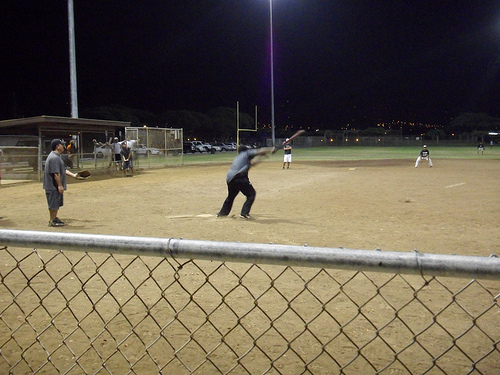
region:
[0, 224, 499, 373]
metal chain link fence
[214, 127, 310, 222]
baseball player in black pants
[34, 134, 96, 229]
large man in grey shorts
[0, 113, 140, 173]
wooden baseball dugout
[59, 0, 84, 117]
large silver metal light pole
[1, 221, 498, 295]
top supporting bar of a chain link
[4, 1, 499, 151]
dark black night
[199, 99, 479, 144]
golden city lights in the distance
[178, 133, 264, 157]
parking lot full of parked cars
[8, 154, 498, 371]
brown dirt base ball field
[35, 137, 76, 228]
man in a gray shirt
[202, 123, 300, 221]
man swinging a baseball bat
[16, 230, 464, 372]
chain link fence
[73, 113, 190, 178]
people in a baseball dugout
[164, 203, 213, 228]
home base on a baseball diamond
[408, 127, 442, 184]
baseball player in white pants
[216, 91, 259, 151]
yellow field goal post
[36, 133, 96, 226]
man holding a brown glove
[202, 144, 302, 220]
man in black pants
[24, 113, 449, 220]
men playing baseball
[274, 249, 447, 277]
Metal fence.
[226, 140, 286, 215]
The man is swinging a baseball bat.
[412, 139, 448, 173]
baseball outfielder.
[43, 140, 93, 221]
A man playing the catcher.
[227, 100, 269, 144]
A field goal.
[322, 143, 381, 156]
A green grass field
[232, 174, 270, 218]
Man wearing black pants.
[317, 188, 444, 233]
Baseball field.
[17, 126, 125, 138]
Baseball dugout.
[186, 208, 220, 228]
Home plate.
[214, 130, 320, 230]
player swinging the bat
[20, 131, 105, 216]
catcher in the game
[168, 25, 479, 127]
it is dark outside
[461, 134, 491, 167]
person in the outfield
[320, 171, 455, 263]
baseball field made of dirt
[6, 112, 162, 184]
players in the dugout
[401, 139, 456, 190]
person is playing short stop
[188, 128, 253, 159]
visitors parked their cars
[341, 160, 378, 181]
third base in baseball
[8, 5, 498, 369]
a baseball game is at night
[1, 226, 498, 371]
a chain link fence is around the field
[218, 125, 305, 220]
a man is swinging the bat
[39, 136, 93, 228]
the catcher is standing behind home base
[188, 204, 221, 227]
home base is near the batter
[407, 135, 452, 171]
a player is ready to act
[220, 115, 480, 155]
lights are on in the background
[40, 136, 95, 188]
the player has a mitt in his hand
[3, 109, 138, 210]
players are in the dugout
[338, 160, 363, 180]
third base in the field